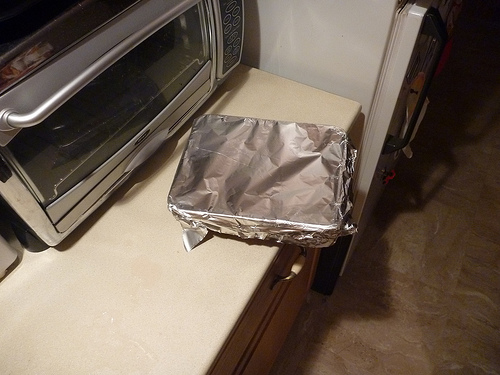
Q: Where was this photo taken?
A: Kitchen.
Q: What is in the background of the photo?
A: Fridge, toaster oven.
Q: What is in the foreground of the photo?
A: Counter top.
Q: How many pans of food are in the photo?
A: One.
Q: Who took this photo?
A: Someone who is about to cook.